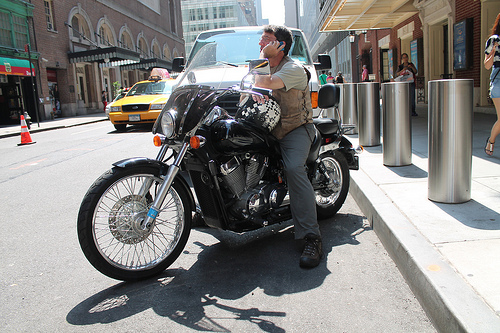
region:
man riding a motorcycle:
[101, 19, 381, 285]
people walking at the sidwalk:
[343, 43, 437, 163]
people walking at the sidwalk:
[342, 42, 395, 122]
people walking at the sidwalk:
[309, 40, 371, 117]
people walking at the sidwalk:
[390, 6, 494, 170]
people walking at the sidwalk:
[337, 34, 429, 93]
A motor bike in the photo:
[73, 60, 346, 283]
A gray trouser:
[282, 143, 322, 237]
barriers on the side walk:
[364, 76, 474, 198]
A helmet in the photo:
[240, 95, 298, 127]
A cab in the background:
[105, 77, 179, 126]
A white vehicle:
[177, 20, 321, 96]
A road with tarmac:
[322, 274, 370, 329]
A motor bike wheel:
[67, 154, 199, 284]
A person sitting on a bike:
[246, 1, 334, 273]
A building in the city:
[40, 2, 167, 98]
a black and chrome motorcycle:
[74, 71, 360, 283]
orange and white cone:
[19, 112, 36, 150]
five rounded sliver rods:
[320, 79, 472, 204]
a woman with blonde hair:
[483, 14, 498, 161]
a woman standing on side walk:
[392, 51, 423, 120]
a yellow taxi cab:
[107, 67, 176, 132]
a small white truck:
[170, 23, 325, 120]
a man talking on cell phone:
[267, 39, 289, 57]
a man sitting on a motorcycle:
[243, 23, 324, 265]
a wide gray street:
[1, 53, 466, 331]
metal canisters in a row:
[335, 75, 474, 203]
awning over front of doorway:
[66, 11, 138, 114]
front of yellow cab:
[110, 68, 180, 129]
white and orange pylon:
[16, 114, 33, 146]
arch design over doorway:
[67, 5, 99, 115]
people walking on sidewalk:
[324, 13, 499, 265]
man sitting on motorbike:
[77, 22, 349, 280]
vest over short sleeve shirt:
[267, 60, 313, 138]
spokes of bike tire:
[91, 165, 190, 269]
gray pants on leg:
[272, 125, 322, 238]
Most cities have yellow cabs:
[101, 67, 176, 128]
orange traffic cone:
[8, 107, 44, 154]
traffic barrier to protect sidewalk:
[423, 77, 475, 206]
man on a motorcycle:
[218, 17, 348, 270]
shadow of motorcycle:
[62, 211, 374, 327]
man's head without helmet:
[247, 24, 297, 66]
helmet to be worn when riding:
[240, 94, 282, 129]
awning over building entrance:
[65, 49, 137, 122]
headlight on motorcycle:
[154, 107, 180, 137]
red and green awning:
[2, 57, 37, 78]